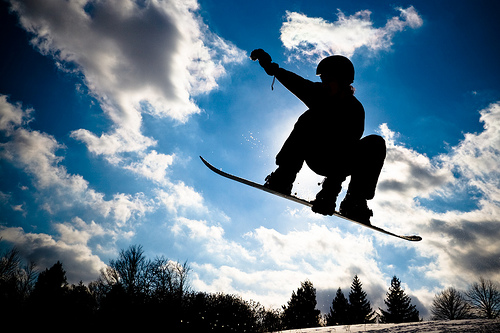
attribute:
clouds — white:
[73, 49, 199, 136]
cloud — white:
[11, 2, 233, 141]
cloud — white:
[367, 121, 499, 292]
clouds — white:
[351, 100, 498, 290]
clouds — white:
[13, 0, 228, 156]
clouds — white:
[301, 21, 381, 63]